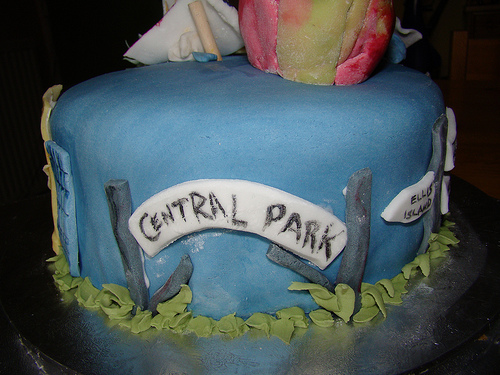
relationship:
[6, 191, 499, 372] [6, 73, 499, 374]
metal tray on a table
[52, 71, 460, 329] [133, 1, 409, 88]
cake with fondant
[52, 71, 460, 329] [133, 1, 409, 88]
cake has decorations